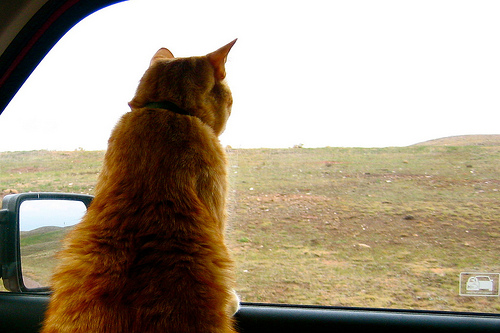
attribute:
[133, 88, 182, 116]
animal — brown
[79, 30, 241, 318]
animal — brown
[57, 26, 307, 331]
animal — brown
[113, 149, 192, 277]
cat — brown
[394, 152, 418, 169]
animal — brown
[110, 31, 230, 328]
animal — brown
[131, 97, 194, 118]
collar — black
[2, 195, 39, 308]
sidemirror — black, side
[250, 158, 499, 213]
grass — small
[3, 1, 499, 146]
sky — white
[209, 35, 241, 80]
ear — raised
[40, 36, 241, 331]
animal — brown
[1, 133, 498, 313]
ground — dry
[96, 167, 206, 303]
cat — orange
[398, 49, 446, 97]
sky — white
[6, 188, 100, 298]
mirror — glass